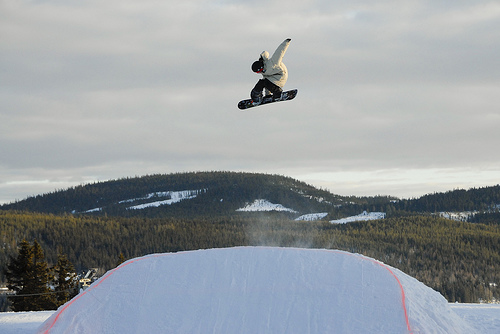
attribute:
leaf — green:
[482, 246, 486, 251]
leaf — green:
[73, 216, 178, 248]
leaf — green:
[368, 225, 399, 237]